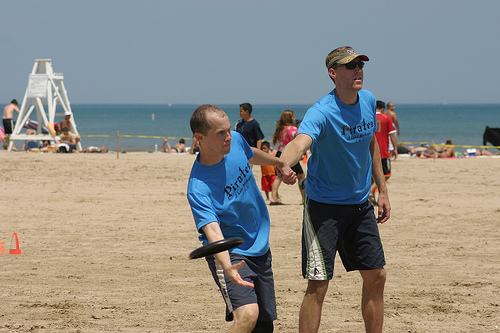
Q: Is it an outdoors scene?
A: Yes, it is outdoors.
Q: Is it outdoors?
A: Yes, it is outdoors.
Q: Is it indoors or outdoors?
A: It is outdoors.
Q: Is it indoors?
A: No, it is outdoors.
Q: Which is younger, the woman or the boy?
A: The boy is younger than the woman.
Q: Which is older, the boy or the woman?
A: The woman is older than the boy.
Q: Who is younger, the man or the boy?
A: The boy is younger than the man.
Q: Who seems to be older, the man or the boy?
A: The man is older than the boy.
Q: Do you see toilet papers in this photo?
A: No, there are no toilet papers.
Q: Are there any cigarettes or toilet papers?
A: No, there are no toilet papers or cigarettes.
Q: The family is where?
A: The family is on the beach.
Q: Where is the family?
A: The family is on the beach.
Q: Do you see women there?
A: Yes, there is a woman.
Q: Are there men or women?
A: Yes, there is a woman.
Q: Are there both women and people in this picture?
A: Yes, there are both a woman and people.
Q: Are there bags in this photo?
A: No, there are no bags.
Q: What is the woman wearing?
A: The woman is wearing a shirt.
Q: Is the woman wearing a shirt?
A: Yes, the woman is wearing a shirt.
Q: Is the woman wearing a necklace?
A: No, the woman is wearing a shirt.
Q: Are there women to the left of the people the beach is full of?
A: Yes, there is a woman to the left of the people.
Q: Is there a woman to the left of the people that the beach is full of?
A: Yes, there is a woman to the left of the people.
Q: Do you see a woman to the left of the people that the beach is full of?
A: Yes, there is a woman to the left of the people.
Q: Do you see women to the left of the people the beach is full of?
A: Yes, there is a woman to the left of the people.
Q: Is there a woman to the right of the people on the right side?
A: No, the woman is to the left of the people.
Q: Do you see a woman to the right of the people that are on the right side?
A: No, the woman is to the left of the people.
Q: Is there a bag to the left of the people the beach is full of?
A: No, there is a woman to the left of the people.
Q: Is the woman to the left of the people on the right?
A: Yes, the woman is to the left of the people.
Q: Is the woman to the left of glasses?
A: No, the woman is to the left of the people.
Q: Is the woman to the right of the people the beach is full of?
A: No, the woman is to the left of the people.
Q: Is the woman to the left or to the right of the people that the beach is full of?
A: The woman is to the left of the people.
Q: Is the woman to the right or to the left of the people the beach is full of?
A: The woman is to the left of the people.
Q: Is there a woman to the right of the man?
A: Yes, there is a woman to the right of the man.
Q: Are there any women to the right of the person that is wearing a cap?
A: Yes, there is a woman to the right of the man.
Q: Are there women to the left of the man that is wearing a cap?
A: No, the woman is to the right of the man.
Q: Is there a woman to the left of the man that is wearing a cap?
A: No, the woman is to the right of the man.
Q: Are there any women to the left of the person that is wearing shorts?
A: No, the woman is to the right of the man.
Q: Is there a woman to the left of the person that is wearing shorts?
A: No, the woman is to the right of the man.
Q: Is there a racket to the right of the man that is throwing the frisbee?
A: No, there is a woman to the right of the man.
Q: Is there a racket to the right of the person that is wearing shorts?
A: No, there is a woman to the right of the man.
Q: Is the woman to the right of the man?
A: Yes, the woman is to the right of the man.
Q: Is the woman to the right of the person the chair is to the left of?
A: Yes, the woman is to the right of the man.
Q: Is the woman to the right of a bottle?
A: No, the woman is to the right of the man.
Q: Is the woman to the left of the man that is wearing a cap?
A: No, the woman is to the right of the man.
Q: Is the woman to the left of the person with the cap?
A: No, the woman is to the right of the man.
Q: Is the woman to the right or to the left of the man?
A: The woman is to the right of the man.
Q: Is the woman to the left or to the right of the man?
A: The woman is to the right of the man.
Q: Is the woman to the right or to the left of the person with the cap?
A: The woman is to the right of the man.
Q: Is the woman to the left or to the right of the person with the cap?
A: The woman is to the right of the man.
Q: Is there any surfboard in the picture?
A: No, there are no surfboards.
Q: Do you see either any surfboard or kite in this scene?
A: No, there are no surfboards or kites.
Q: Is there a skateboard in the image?
A: No, there are no skateboards.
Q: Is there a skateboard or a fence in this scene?
A: No, there are no skateboards or fences.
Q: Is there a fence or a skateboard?
A: No, there are no skateboards or fences.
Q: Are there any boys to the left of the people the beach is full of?
A: Yes, there is a boy to the left of the people.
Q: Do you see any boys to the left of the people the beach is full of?
A: Yes, there is a boy to the left of the people.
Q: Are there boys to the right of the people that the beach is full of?
A: No, the boy is to the left of the people.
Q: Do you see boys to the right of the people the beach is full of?
A: No, the boy is to the left of the people.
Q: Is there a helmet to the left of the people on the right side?
A: No, there is a boy to the left of the people.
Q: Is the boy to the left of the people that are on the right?
A: Yes, the boy is to the left of the people.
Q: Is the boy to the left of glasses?
A: No, the boy is to the left of the people.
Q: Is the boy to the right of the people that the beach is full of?
A: No, the boy is to the left of the people.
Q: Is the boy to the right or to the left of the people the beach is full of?
A: The boy is to the left of the people.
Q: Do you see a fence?
A: No, there are no fences.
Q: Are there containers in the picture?
A: No, there are no containers.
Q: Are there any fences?
A: No, there are no fences.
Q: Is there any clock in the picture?
A: No, there are no clocks.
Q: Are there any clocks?
A: No, there are no clocks.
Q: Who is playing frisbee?
A: The man is playing frisbee.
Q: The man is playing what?
A: The man is playing frisbee.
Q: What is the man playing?
A: The man is playing frisbee.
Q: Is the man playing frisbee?
A: Yes, the man is playing frisbee.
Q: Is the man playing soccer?
A: No, the man is playing frisbee.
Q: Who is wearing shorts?
A: The man is wearing shorts.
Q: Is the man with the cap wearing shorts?
A: Yes, the man is wearing shorts.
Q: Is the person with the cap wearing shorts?
A: Yes, the man is wearing shorts.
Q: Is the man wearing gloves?
A: No, the man is wearing shorts.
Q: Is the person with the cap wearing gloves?
A: No, the man is wearing shorts.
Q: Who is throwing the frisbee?
A: The man is throwing the frisbee.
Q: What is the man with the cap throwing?
A: The man is throwing the frisbee.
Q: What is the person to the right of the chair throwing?
A: The man is throwing the frisbee.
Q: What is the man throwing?
A: The man is throwing the frisbee.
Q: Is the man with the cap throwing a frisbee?
A: Yes, the man is throwing a frisbee.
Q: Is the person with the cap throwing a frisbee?
A: Yes, the man is throwing a frisbee.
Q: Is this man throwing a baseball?
A: No, the man is throwing a frisbee.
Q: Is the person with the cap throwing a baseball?
A: No, the man is throwing a frisbee.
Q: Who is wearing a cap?
A: The man is wearing a cap.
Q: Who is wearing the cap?
A: The man is wearing a cap.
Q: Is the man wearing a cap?
A: Yes, the man is wearing a cap.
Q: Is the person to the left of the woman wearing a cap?
A: Yes, the man is wearing a cap.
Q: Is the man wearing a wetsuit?
A: No, the man is wearing a cap.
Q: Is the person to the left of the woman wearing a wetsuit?
A: No, the man is wearing a cap.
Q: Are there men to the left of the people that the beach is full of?
A: Yes, there is a man to the left of the people.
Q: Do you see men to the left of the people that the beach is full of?
A: Yes, there is a man to the left of the people.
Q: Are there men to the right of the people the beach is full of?
A: No, the man is to the left of the people.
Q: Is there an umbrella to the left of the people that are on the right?
A: No, there is a man to the left of the people.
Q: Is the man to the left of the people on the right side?
A: Yes, the man is to the left of the people.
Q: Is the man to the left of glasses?
A: No, the man is to the left of the people.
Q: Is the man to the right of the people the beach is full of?
A: No, the man is to the left of the people.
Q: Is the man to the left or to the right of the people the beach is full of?
A: The man is to the left of the people.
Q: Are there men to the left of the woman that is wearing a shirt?
A: Yes, there is a man to the left of the woman.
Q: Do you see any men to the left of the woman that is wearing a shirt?
A: Yes, there is a man to the left of the woman.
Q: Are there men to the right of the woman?
A: No, the man is to the left of the woman.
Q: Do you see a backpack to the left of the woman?
A: No, there is a man to the left of the woman.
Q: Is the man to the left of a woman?
A: Yes, the man is to the left of a woman.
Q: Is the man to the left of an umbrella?
A: No, the man is to the left of a woman.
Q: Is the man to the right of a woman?
A: No, the man is to the left of a woman.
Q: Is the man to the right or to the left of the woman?
A: The man is to the left of the woman.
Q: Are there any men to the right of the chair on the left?
A: Yes, there is a man to the right of the chair.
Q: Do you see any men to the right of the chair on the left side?
A: Yes, there is a man to the right of the chair.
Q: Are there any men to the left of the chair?
A: No, the man is to the right of the chair.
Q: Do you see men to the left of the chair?
A: No, the man is to the right of the chair.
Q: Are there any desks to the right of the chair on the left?
A: No, there is a man to the right of the chair.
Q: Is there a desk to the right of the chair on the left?
A: No, there is a man to the right of the chair.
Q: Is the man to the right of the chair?
A: Yes, the man is to the right of the chair.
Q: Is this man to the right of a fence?
A: No, the man is to the right of the chair.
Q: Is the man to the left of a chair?
A: No, the man is to the right of a chair.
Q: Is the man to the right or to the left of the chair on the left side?
A: The man is to the right of the chair.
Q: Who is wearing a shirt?
A: The man is wearing a shirt.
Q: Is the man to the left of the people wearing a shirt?
A: Yes, the man is wearing a shirt.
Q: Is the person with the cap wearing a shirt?
A: Yes, the man is wearing a shirt.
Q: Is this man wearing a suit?
A: No, the man is wearing a shirt.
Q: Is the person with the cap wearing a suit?
A: No, the man is wearing a shirt.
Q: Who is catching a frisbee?
A: The man is catching a frisbee.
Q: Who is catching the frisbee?
A: The man is catching a frisbee.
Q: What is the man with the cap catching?
A: The man is catching a frisbee.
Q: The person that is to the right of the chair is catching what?
A: The man is catching a frisbee.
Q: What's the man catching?
A: The man is catching a frisbee.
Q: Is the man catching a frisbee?
A: Yes, the man is catching a frisbee.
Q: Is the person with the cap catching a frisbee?
A: Yes, the man is catching a frisbee.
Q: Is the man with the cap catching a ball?
A: No, the man is catching a frisbee.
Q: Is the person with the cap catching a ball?
A: No, the man is catching a frisbee.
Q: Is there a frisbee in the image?
A: Yes, there is a frisbee.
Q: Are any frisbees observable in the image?
A: Yes, there is a frisbee.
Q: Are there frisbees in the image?
A: Yes, there is a frisbee.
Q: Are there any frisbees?
A: Yes, there is a frisbee.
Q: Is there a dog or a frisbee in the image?
A: Yes, there is a frisbee.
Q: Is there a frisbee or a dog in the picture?
A: Yes, there is a frisbee.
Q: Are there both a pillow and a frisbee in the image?
A: No, there is a frisbee but no pillows.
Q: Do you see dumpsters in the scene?
A: No, there are no dumpsters.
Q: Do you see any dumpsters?
A: No, there are no dumpsters.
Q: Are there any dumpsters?
A: No, there are no dumpsters.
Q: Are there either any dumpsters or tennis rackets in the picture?
A: No, there are no dumpsters or tennis rackets.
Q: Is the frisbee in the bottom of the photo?
A: Yes, the frisbee is in the bottom of the image.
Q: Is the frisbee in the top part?
A: No, the frisbee is in the bottom of the image.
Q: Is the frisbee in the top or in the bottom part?
A: The frisbee is in the bottom of the image.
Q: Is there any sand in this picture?
A: Yes, there is sand.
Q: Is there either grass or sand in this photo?
A: Yes, there is sand.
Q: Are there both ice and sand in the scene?
A: No, there is sand but no ice.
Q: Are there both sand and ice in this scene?
A: No, there is sand but no ice.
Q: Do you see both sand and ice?
A: No, there is sand but no ice.